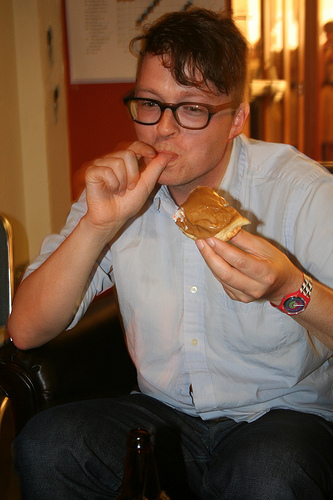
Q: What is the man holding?
A: A donut.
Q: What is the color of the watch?
A: Red, with a white and black band.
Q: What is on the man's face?
A: Glasses.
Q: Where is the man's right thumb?
A: In the man's mouth.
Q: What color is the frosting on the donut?
A: Brown.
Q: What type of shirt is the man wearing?
A: A button down.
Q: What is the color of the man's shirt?
A: Blue.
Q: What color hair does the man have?
A: Brown.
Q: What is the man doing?
A: Eating.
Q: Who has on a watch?
A: The man.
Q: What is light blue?
A: Man's shirt.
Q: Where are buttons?
A: On shirt.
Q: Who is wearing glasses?
A: A man.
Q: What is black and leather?
A: Couch.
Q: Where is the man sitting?
A: On a couch.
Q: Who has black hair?
A: The man.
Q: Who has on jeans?
A: A man.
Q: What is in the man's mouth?
A: Man's thumb.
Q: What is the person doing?
A: Eating.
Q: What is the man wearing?
A: Glasses.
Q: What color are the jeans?
A: Black.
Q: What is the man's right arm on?
A: Leather chair.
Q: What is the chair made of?
A: Leather.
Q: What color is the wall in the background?
A: Red.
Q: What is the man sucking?
A: Thumb.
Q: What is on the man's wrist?
A: A watch.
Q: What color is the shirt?
A: Blue.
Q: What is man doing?
A: Licking his thumb.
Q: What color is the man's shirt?
A: Blue.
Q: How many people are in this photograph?
A: One.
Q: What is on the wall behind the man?
A: A whiteboard.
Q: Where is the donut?
A: In the man's hand.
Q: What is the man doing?
A: Eating.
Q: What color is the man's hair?
A: Brown.